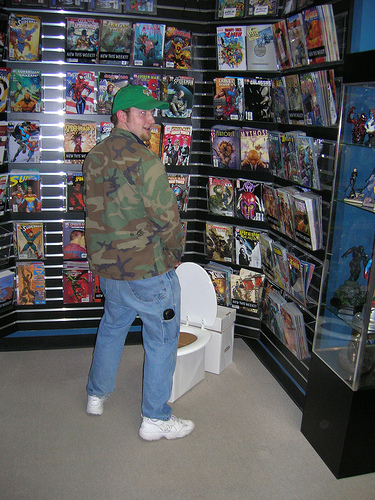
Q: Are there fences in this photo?
A: No, there are no fences.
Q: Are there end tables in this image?
A: No, there are no end tables.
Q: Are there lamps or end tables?
A: No, there are no end tables or lamps.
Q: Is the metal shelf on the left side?
A: Yes, the shelf is on the left of the image.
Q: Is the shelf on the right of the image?
A: No, the shelf is on the left of the image.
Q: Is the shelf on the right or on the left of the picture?
A: The shelf is on the left of the image.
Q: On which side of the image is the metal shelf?
A: The shelf is on the left of the image.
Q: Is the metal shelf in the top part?
A: Yes, the shelf is in the top of the image.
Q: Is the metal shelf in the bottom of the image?
A: No, the shelf is in the top of the image.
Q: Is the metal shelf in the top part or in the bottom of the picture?
A: The shelf is in the top of the image.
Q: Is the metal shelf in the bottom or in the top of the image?
A: The shelf is in the top of the image.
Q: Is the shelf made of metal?
A: Yes, the shelf is made of metal.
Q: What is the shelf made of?
A: The shelf is made of metal.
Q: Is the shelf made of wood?
A: No, the shelf is made of metal.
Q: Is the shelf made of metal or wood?
A: The shelf is made of metal.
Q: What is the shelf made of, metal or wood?
A: The shelf is made of metal.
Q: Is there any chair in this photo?
A: No, there are no chairs.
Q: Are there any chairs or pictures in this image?
A: No, there are no chairs or pictures.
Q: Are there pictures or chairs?
A: No, there are no chairs or pictures.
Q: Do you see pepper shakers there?
A: No, there are no pepper shakers.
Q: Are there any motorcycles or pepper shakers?
A: No, there are no pepper shakers or motorcycles.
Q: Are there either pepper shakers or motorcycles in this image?
A: No, there are no pepper shakers or motorcycles.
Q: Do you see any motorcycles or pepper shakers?
A: No, there are no pepper shakers or motorcycles.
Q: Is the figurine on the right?
A: Yes, the figurine is on the right of the image.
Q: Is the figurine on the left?
A: No, the figurine is on the right of the image.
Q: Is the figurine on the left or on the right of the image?
A: The figurine is on the right of the image.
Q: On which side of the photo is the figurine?
A: The figurine is on the right of the image.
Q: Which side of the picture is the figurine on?
A: The figurine is on the right of the image.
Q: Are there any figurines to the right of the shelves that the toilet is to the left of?
A: Yes, there is a figurine to the right of the shelves.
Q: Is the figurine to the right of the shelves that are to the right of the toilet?
A: Yes, the figurine is to the right of the shelves.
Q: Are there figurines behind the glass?
A: Yes, there is a figurine behind the glass.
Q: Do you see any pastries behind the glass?
A: No, there is a figurine behind the glass.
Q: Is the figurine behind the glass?
A: Yes, the figurine is behind the glass.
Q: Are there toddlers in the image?
A: No, there are no toddlers.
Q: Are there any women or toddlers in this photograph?
A: No, there are no toddlers or women.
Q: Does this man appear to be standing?
A: Yes, the man is standing.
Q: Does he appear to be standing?
A: Yes, the man is standing.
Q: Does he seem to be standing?
A: Yes, the man is standing.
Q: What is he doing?
A: The man is standing.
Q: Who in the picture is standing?
A: The man is standing.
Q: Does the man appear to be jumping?
A: No, the man is standing.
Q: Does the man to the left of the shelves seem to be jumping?
A: No, the man is standing.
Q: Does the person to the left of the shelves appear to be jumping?
A: No, the man is standing.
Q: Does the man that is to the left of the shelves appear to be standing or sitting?
A: The man is standing.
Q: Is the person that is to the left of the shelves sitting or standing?
A: The man is standing.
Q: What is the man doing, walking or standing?
A: The man is standing.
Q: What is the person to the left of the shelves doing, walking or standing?
A: The man is standing.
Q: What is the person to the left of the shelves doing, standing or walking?
A: The man is standing.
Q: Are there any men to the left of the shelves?
A: Yes, there is a man to the left of the shelves.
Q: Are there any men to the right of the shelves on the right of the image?
A: No, the man is to the left of the shelves.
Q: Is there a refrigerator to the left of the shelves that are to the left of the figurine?
A: No, there is a man to the left of the shelves.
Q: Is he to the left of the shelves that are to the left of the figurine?
A: Yes, the man is to the left of the shelves.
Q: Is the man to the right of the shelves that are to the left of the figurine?
A: No, the man is to the left of the shelves.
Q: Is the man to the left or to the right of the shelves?
A: The man is to the left of the shelves.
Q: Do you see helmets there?
A: No, there are no helmets.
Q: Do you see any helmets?
A: No, there are no helmets.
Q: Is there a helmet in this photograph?
A: No, there are no helmets.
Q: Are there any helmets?
A: No, there are no helmets.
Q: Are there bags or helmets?
A: No, there are no helmets or bags.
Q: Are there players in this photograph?
A: No, there are no players.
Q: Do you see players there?
A: No, there are no players.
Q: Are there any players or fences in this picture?
A: No, there are no players or fences.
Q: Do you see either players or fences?
A: No, there are no players or fences.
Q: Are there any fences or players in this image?
A: No, there are no players or fences.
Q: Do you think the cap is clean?
A: Yes, the cap is clean.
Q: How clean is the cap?
A: The cap is clean.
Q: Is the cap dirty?
A: No, the cap is clean.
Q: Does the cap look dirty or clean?
A: The cap is clean.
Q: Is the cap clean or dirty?
A: The cap is clean.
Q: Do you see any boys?
A: No, there are no boys.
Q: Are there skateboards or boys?
A: No, there are no boys or skateboards.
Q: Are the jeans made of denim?
A: Yes, the jeans are made of denim.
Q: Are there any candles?
A: No, there are no candles.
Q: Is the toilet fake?
A: Yes, the toilet is fake.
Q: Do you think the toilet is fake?
A: Yes, the toilet is fake.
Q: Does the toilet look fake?
A: Yes, the toilet is fake.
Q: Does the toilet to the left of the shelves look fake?
A: Yes, the toilet is fake.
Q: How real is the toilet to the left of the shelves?
A: The toilet is fake.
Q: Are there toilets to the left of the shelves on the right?
A: Yes, there is a toilet to the left of the shelves.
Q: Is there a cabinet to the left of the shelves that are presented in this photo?
A: No, there is a toilet to the left of the shelves.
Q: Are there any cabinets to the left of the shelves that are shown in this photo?
A: No, there is a toilet to the left of the shelves.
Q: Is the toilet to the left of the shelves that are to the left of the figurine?
A: Yes, the toilet is to the left of the shelves.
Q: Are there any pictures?
A: No, there are no pictures.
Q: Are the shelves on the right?
A: Yes, the shelves are on the right of the image.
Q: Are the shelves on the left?
A: No, the shelves are on the right of the image.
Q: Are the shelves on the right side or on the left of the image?
A: The shelves are on the right of the image.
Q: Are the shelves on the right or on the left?
A: The shelves are on the right of the image.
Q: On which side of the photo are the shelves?
A: The shelves are on the right of the image.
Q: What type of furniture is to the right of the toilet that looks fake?
A: The pieces of furniture are shelves.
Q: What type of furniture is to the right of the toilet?
A: The pieces of furniture are shelves.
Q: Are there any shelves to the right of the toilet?
A: Yes, there are shelves to the right of the toilet.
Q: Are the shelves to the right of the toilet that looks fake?
A: Yes, the shelves are to the right of the toilet.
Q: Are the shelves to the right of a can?
A: No, the shelves are to the right of the toilet.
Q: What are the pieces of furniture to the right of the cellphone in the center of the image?
A: The pieces of furniture are shelves.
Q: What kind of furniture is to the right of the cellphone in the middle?
A: The pieces of furniture are shelves.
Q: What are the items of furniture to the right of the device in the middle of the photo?
A: The pieces of furniture are shelves.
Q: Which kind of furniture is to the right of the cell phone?
A: The pieces of furniture are shelves.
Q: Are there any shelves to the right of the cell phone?
A: Yes, there are shelves to the right of the cell phone.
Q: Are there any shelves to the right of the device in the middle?
A: Yes, there are shelves to the right of the cell phone.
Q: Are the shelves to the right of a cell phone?
A: Yes, the shelves are to the right of a cell phone.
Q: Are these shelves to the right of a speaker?
A: No, the shelves are to the right of a cell phone.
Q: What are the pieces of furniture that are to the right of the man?
A: The pieces of furniture are shelves.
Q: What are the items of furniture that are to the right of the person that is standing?
A: The pieces of furniture are shelves.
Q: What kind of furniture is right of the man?
A: The pieces of furniture are shelves.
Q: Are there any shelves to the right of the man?
A: Yes, there are shelves to the right of the man.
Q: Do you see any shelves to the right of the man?
A: Yes, there are shelves to the right of the man.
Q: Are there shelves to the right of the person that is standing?
A: Yes, there are shelves to the right of the man.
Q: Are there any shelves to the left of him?
A: No, the shelves are to the right of the man.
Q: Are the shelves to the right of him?
A: Yes, the shelves are to the right of a man.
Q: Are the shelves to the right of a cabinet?
A: No, the shelves are to the right of a man.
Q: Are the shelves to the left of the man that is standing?
A: No, the shelves are to the right of the man.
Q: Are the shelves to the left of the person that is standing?
A: No, the shelves are to the right of the man.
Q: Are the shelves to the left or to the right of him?
A: The shelves are to the right of the man.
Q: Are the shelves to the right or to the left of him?
A: The shelves are to the right of the man.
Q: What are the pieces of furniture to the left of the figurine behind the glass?
A: The pieces of furniture are shelves.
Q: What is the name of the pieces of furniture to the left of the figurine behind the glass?
A: The pieces of furniture are shelves.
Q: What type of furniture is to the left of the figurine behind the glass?
A: The pieces of furniture are shelves.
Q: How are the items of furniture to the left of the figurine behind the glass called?
A: The pieces of furniture are shelves.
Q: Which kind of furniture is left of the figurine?
A: The pieces of furniture are shelves.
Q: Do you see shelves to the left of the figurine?
A: Yes, there are shelves to the left of the figurine.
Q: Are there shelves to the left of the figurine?
A: Yes, there are shelves to the left of the figurine.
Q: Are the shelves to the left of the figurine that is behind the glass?
A: Yes, the shelves are to the left of the figurine.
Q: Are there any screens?
A: No, there are no screens.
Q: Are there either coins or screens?
A: No, there are no screens or coins.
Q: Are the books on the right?
A: Yes, the books are on the right of the image.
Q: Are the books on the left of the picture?
A: No, the books are on the right of the image.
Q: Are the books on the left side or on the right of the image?
A: The books are on the right of the image.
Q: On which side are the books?
A: The books are on the right of the image.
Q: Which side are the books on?
A: The books are on the right of the image.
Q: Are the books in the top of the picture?
A: Yes, the books are in the top of the image.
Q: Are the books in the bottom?
A: No, the books are in the top of the image.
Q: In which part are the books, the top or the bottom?
A: The books are in the top of the image.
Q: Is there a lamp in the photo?
A: No, there are no lamps.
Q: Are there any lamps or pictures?
A: No, there are no lamps or pictures.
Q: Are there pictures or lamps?
A: No, there are no lamps or pictures.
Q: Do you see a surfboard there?
A: No, there are no surfboards.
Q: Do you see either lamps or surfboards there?
A: No, there are no surfboards or lamps.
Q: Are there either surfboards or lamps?
A: No, there are no surfboards or lamps.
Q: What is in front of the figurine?
A: The glass is in front of the figurine.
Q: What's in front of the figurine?
A: The glass is in front of the figurine.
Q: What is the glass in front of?
A: The glass is in front of the figurine.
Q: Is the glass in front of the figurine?
A: Yes, the glass is in front of the figurine.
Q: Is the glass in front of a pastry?
A: No, the glass is in front of the figurine.